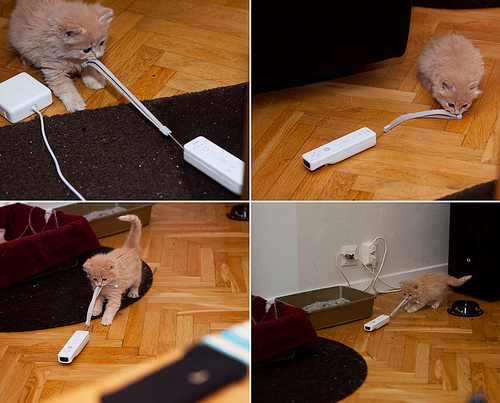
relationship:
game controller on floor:
[302, 126, 376, 171] [249, 104, 498, 201]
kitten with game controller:
[78, 208, 150, 331] [294, 108, 459, 173]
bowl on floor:
[449, 296, 481, 318] [260, 287, 499, 401]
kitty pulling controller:
[7, 0, 112, 113] [56, 285, 102, 365]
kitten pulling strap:
[83, 213, 142, 326] [83, 285, 100, 328]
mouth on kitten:
[95, 284, 103, 288] [83, 213, 142, 326]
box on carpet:
[252, 293, 319, 360] [3, 242, 158, 340]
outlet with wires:
[341, 244, 359, 266] [347, 261, 420, 309]